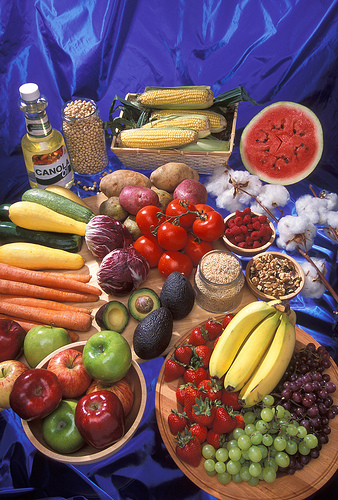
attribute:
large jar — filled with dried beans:
[61, 94, 108, 176]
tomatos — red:
[141, 205, 197, 259]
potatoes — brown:
[101, 170, 152, 199]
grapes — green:
[199, 395, 318, 487]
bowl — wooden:
[243, 248, 305, 303]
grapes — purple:
[279, 341, 326, 445]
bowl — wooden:
[217, 209, 276, 258]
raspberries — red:
[225, 205, 271, 248]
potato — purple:
[118, 183, 159, 212]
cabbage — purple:
[83, 212, 129, 255]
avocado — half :
[89, 296, 128, 332]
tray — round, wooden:
[152, 309, 326, 497]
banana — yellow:
[207, 298, 275, 380]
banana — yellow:
[222, 308, 280, 394]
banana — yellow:
[235, 309, 296, 409]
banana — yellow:
[284, 307, 298, 327]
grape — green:
[235, 432, 251, 451]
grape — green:
[261, 433, 273, 446]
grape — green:
[272, 434, 289, 451]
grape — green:
[247, 461, 262, 476]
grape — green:
[211, 459, 227, 474]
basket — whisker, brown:
[110, 90, 239, 174]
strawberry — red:
[166, 408, 188, 435]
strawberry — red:
[182, 383, 207, 411]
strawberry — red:
[163, 355, 185, 382]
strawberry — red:
[190, 344, 212, 366]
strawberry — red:
[203, 317, 223, 340]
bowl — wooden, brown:
[20, 339, 147, 464]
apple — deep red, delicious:
[73, 388, 127, 448]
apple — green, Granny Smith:
[80, 329, 133, 383]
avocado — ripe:
[131, 306, 174, 360]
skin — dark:
[131, 305, 174, 360]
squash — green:
[0, 221, 83, 250]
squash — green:
[20, 186, 94, 224]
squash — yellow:
[1, 241, 87, 270]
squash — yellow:
[6, 200, 87, 235]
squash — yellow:
[43, 183, 97, 214]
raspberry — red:
[234, 215, 243, 225]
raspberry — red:
[230, 223, 241, 235]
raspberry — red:
[245, 222, 254, 229]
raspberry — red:
[256, 213, 267, 222]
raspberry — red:
[252, 239, 261, 247]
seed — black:
[273, 124, 276, 129]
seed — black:
[255, 138, 260, 142]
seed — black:
[298, 142, 304, 146]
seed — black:
[291, 128, 297, 134]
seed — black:
[271, 162, 276, 166]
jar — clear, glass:
[60, 96, 110, 177]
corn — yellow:
[137, 87, 213, 104]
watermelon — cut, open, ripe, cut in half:
[237, 100, 324, 186]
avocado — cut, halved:
[93, 299, 130, 334]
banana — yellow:
[285, 303, 296, 327]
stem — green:
[172, 425, 195, 448]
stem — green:
[167, 408, 189, 420]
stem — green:
[168, 353, 187, 365]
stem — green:
[171, 341, 192, 347]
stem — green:
[198, 323, 210, 340]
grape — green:
[228, 445, 242, 462]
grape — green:
[246, 444, 263, 463]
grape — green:
[250, 430, 264, 444]